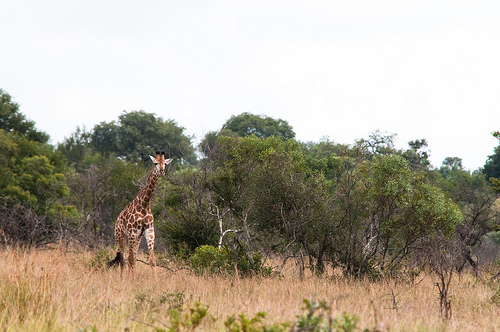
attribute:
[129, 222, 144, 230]
skin — brown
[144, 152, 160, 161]
ear — white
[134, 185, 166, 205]
neck — long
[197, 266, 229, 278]
grass — dry, green, long, tall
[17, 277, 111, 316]
plants — small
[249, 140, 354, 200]
trees — here, green, acacia, white, grey, thick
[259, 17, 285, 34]
sky — blue, gray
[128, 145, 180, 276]
giraffe — standing, tall, fuzzy, here, walking, brown, chest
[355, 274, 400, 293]
twigs — dry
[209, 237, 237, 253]
bark — white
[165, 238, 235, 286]
bush — here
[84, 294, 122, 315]
weeds — dry